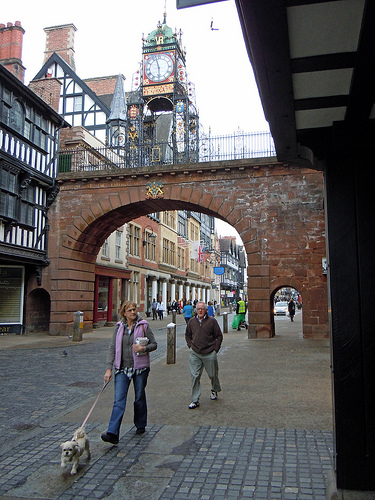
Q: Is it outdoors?
A: Yes, it is outdoors.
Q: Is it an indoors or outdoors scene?
A: It is outdoors.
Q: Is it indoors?
A: No, it is outdoors.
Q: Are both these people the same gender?
A: No, they are both male and female.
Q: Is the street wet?
A: Yes, the street is wet.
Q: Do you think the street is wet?
A: Yes, the street is wet.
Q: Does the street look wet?
A: Yes, the street is wet.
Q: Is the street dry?
A: No, the street is wet.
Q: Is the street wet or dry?
A: The street is wet.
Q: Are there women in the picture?
A: Yes, there is a woman.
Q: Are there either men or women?
A: Yes, there is a woman.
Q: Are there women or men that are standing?
A: Yes, the woman is standing.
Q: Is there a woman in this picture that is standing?
A: Yes, there is a woman that is standing.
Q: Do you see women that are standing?
A: Yes, there is a woman that is standing.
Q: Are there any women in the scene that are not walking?
A: Yes, there is a woman that is standing.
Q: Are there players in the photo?
A: No, there are no players.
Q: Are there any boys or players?
A: No, there are no players or boys.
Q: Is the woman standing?
A: Yes, the woman is standing.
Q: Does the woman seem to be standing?
A: Yes, the woman is standing.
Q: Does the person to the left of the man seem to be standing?
A: Yes, the woman is standing.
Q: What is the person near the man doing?
A: The woman is standing.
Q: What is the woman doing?
A: The woman is standing.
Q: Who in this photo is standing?
A: The woman is standing.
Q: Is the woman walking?
A: No, the woman is standing.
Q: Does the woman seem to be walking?
A: No, the woman is standing.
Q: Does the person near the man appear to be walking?
A: No, the woman is standing.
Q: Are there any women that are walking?
A: No, there is a woman but she is standing.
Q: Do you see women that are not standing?
A: No, there is a woman but she is standing.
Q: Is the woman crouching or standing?
A: The woman is standing.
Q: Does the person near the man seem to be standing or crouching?
A: The woman is standing.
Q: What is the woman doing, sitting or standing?
A: The woman is standing.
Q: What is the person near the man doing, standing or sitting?
A: The woman is standing.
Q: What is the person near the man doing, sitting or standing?
A: The woman is standing.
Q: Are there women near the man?
A: Yes, there is a woman near the man.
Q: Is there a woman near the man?
A: Yes, there is a woman near the man.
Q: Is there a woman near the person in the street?
A: Yes, there is a woman near the man.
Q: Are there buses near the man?
A: No, there is a woman near the man.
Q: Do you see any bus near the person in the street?
A: No, there is a woman near the man.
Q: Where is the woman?
A: The woman is on the street.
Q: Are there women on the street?
A: Yes, there is a woman on the street.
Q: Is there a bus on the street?
A: No, there is a woman on the street.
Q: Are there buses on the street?
A: No, there is a woman on the street.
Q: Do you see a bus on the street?
A: No, there is a woman on the street.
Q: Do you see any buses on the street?
A: No, there is a woman on the street.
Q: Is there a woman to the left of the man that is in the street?
A: Yes, there is a woman to the left of the man.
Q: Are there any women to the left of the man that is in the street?
A: Yes, there is a woman to the left of the man.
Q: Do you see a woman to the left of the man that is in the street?
A: Yes, there is a woman to the left of the man.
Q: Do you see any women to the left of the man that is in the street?
A: Yes, there is a woman to the left of the man.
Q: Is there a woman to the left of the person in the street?
A: Yes, there is a woman to the left of the man.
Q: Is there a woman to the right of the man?
A: No, the woman is to the left of the man.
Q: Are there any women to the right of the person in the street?
A: No, the woman is to the left of the man.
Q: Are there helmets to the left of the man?
A: No, there is a woman to the left of the man.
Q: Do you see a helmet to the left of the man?
A: No, there is a woman to the left of the man.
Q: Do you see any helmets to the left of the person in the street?
A: No, there is a woman to the left of the man.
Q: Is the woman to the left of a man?
A: Yes, the woman is to the left of a man.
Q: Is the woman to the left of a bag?
A: No, the woman is to the left of a man.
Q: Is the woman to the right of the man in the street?
A: No, the woman is to the left of the man.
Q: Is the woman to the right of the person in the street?
A: No, the woman is to the left of the man.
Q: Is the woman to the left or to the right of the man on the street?
A: The woman is to the left of the man.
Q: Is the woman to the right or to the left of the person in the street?
A: The woman is to the left of the man.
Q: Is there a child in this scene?
A: No, there are no children.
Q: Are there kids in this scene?
A: No, there are no kids.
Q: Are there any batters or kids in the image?
A: No, there are no kids or batters.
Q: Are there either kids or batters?
A: No, there are no kids or batters.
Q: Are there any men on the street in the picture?
A: Yes, there is a man on the street.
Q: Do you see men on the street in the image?
A: Yes, there is a man on the street.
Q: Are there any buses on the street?
A: No, there is a man on the street.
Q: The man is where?
A: The man is in the street.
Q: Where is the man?
A: The man is in the street.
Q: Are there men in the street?
A: Yes, there is a man in the street.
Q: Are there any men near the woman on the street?
A: Yes, there is a man near the woman.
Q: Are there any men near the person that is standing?
A: Yes, there is a man near the woman.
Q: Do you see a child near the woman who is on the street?
A: No, there is a man near the woman.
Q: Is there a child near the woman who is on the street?
A: No, there is a man near the woman.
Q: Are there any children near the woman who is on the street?
A: No, there is a man near the woman.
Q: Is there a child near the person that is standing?
A: No, there is a man near the woman.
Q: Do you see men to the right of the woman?
A: Yes, there is a man to the right of the woman.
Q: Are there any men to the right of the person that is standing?
A: Yes, there is a man to the right of the woman.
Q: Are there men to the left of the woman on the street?
A: No, the man is to the right of the woman.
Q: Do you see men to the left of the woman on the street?
A: No, the man is to the right of the woman.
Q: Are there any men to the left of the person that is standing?
A: No, the man is to the right of the woman.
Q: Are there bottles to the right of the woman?
A: No, there is a man to the right of the woman.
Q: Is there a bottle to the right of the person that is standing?
A: No, there is a man to the right of the woman.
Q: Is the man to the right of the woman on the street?
A: Yes, the man is to the right of the woman.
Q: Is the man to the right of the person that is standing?
A: Yes, the man is to the right of the woman.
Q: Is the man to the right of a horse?
A: No, the man is to the right of the woman.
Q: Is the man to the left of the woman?
A: No, the man is to the right of the woman.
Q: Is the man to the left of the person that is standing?
A: No, the man is to the right of the woman.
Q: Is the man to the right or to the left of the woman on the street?
A: The man is to the right of the woman.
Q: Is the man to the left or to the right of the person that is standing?
A: The man is to the right of the woman.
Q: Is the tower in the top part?
A: Yes, the tower is in the top of the image.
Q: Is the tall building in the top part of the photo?
A: Yes, the tower is in the top of the image.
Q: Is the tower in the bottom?
A: No, the tower is in the top of the image.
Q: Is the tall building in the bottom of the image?
A: No, the tower is in the top of the image.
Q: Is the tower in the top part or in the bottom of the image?
A: The tower is in the top of the image.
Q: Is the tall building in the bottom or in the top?
A: The tower is in the top of the image.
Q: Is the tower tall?
A: Yes, the tower is tall.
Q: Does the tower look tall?
A: Yes, the tower is tall.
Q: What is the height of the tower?
A: The tower is tall.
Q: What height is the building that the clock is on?
A: The tower is tall.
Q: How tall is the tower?
A: The tower is tall.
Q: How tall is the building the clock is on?
A: The tower is tall.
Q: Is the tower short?
A: No, the tower is tall.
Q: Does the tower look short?
A: No, the tower is tall.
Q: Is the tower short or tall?
A: The tower is tall.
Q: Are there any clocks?
A: Yes, there is a clock.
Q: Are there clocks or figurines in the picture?
A: Yes, there is a clock.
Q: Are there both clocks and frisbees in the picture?
A: No, there is a clock but no frisbees.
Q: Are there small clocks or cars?
A: Yes, there is a small clock.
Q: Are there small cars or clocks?
A: Yes, there is a small clock.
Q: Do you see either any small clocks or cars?
A: Yes, there is a small clock.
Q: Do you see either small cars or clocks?
A: Yes, there is a small clock.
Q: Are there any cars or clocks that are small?
A: Yes, the clock is small.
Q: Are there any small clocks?
A: Yes, there is a small clock.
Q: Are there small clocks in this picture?
A: Yes, there is a small clock.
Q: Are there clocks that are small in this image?
A: Yes, there is a small clock.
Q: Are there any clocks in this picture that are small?
A: Yes, there is a clock that is small.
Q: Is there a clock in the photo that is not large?
A: Yes, there is a small clock.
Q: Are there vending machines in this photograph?
A: No, there are no vending machines.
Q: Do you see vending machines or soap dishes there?
A: No, there are no vending machines or soap dishes.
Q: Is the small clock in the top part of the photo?
A: Yes, the clock is in the top of the image.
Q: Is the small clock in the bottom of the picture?
A: No, the clock is in the top of the image.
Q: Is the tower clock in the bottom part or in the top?
A: The clock is in the top of the image.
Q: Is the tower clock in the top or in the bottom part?
A: The clock is in the top of the image.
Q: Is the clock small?
A: Yes, the clock is small.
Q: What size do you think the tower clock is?
A: The clock is small.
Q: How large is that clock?
A: The clock is small.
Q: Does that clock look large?
A: No, the clock is small.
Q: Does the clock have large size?
A: No, the clock is small.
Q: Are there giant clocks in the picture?
A: No, there is a clock but it is small.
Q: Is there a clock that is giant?
A: No, there is a clock but it is small.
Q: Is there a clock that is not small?
A: No, there is a clock but it is small.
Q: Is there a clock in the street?
A: Yes, there is a clock in the street.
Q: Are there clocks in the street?
A: Yes, there is a clock in the street.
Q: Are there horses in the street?
A: No, there is a clock in the street.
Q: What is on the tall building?
A: The clock is on the tower.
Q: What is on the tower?
A: The clock is on the tower.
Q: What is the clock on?
A: The clock is on the tower.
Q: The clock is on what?
A: The clock is on the tower.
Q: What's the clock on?
A: The clock is on the tower.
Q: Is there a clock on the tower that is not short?
A: Yes, there is a clock on the tower.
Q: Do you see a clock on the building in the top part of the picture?
A: Yes, there is a clock on the tower.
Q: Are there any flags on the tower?
A: No, there is a clock on the tower.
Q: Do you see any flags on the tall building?
A: No, there is a clock on the tower.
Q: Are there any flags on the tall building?
A: No, there is a clock on the tower.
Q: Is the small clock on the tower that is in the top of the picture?
A: Yes, the clock is on the tower.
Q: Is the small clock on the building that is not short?
A: Yes, the clock is on the tower.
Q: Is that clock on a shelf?
A: No, the clock is on the tower.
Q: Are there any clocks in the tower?
A: Yes, there is a clock in the tower.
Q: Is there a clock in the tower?
A: Yes, there is a clock in the tower.